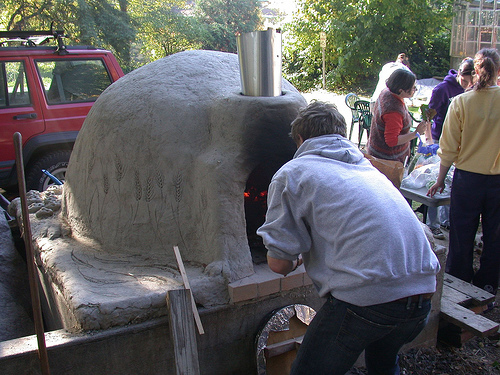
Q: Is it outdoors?
A: Yes, it is outdoors.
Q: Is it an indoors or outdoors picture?
A: It is outdoors.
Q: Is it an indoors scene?
A: No, it is outdoors.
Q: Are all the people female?
A: No, they are both male and female.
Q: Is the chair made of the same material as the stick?
A: No, the chair is made of plastic and the stick is made of wood.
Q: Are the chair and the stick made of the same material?
A: No, the chair is made of plastic and the stick is made of wood.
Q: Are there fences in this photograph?
A: No, there are no fences.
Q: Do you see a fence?
A: No, there are no fences.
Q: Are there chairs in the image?
A: Yes, there is a chair.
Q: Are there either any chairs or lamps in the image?
A: Yes, there is a chair.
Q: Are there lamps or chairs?
A: Yes, there is a chair.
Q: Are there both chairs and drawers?
A: No, there is a chair but no drawers.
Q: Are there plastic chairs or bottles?
A: Yes, there is a plastic chair.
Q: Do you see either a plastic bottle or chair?
A: Yes, there is a plastic chair.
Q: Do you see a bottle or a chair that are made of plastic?
A: Yes, the chair is made of plastic.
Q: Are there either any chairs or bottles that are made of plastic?
A: Yes, the chair is made of plastic.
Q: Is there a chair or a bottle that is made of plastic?
A: Yes, the chair is made of plastic.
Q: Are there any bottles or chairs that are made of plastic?
A: Yes, the chair is made of plastic.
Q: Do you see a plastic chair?
A: Yes, there is a chair that is made of plastic.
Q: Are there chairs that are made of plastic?
A: Yes, there is a chair that is made of plastic.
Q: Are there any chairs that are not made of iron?
A: Yes, there is a chair that is made of plastic.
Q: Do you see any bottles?
A: No, there are no bottles.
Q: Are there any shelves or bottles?
A: No, there are no bottles or shelves.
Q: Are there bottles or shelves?
A: No, there are no bottles or shelves.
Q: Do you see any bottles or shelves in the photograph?
A: No, there are no bottles or shelves.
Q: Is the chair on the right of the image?
A: Yes, the chair is on the right of the image.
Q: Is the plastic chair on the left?
A: No, the chair is on the right of the image.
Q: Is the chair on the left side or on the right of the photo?
A: The chair is on the right of the image.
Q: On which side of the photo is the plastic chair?
A: The chair is on the right of the image.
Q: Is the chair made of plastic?
A: Yes, the chair is made of plastic.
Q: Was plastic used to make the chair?
A: Yes, the chair is made of plastic.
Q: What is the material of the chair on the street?
A: The chair is made of plastic.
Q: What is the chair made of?
A: The chair is made of plastic.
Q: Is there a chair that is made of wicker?
A: No, there is a chair but it is made of plastic.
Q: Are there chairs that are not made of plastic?
A: No, there is a chair but it is made of plastic.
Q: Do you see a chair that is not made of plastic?
A: No, there is a chair but it is made of plastic.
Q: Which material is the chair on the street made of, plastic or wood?
A: The chair is made of plastic.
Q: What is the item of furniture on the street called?
A: The piece of furniture is a chair.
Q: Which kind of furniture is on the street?
A: The piece of furniture is a chair.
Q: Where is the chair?
A: The chair is on the street.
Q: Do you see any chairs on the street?
A: Yes, there is a chair on the street.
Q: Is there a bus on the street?
A: No, there is a chair on the street.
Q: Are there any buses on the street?
A: No, there is a chair on the street.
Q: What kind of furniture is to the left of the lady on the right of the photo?
A: The piece of furniture is a chair.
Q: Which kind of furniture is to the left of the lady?
A: The piece of furniture is a chair.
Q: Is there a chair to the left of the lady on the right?
A: Yes, there is a chair to the left of the lady.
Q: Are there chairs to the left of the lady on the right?
A: Yes, there is a chair to the left of the lady.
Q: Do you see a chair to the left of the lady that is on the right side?
A: Yes, there is a chair to the left of the lady.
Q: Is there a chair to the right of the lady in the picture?
A: No, the chair is to the left of the lady.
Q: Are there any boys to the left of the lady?
A: No, there is a chair to the left of the lady.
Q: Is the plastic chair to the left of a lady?
A: Yes, the chair is to the left of a lady.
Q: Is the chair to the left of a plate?
A: No, the chair is to the left of a lady.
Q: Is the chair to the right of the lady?
A: No, the chair is to the left of the lady.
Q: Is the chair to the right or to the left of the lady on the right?
A: The chair is to the left of the lady.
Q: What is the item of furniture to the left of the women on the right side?
A: The piece of furniture is a chair.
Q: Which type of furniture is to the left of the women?
A: The piece of furniture is a chair.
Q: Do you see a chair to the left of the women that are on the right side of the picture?
A: Yes, there is a chair to the left of the women.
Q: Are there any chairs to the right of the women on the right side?
A: No, the chair is to the left of the women.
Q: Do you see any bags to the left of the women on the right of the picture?
A: No, there is a chair to the left of the women.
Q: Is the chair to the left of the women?
A: Yes, the chair is to the left of the women.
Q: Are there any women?
A: Yes, there are women.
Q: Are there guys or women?
A: Yes, there are women.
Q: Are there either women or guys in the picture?
A: Yes, there are women.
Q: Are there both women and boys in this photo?
A: No, there are women but no boys.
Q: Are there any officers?
A: No, there are no officers.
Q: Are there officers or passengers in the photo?
A: No, there are no officers or passengers.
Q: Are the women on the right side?
A: Yes, the women are on the right of the image.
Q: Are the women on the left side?
A: No, the women are on the right of the image.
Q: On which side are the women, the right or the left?
A: The women are on the right of the image.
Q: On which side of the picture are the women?
A: The women are on the right of the image.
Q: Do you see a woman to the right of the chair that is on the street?
A: Yes, there are women to the right of the chair.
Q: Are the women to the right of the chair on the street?
A: Yes, the women are to the right of the chair.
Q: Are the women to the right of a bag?
A: No, the women are to the right of the chair.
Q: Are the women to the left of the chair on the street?
A: No, the women are to the right of the chair.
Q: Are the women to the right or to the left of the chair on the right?
A: The women are to the right of the chair.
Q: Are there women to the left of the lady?
A: Yes, there are women to the left of the lady.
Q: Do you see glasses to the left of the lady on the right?
A: No, there are women to the left of the lady.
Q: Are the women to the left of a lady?
A: Yes, the women are to the left of a lady.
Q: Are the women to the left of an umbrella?
A: No, the women are to the left of a lady.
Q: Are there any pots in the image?
A: No, there are no pots.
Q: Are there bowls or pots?
A: No, there are no pots or bowls.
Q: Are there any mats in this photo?
A: No, there are no mats.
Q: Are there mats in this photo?
A: No, there are no mats.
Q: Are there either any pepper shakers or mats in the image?
A: No, there are no mats or pepper shakers.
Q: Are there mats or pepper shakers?
A: No, there are no mats or pepper shakers.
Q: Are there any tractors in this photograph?
A: No, there are no tractors.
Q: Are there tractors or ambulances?
A: No, there are no tractors or ambulances.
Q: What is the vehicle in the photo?
A: The vehicle is a car.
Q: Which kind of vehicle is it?
A: The vehicle is a car.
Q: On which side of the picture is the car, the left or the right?
A: The car is on the left of the image.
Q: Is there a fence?
A: No, there are no fences.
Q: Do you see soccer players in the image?
A: No, there are no soccer players.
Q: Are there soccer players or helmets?
A: No, there are no soccer players or helmets.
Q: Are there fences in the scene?
A: No, there are no fences.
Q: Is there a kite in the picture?
A: No, there are no kites.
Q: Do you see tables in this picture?
A: Yes, there is a table.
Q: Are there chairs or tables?
A: Yes, there is a table.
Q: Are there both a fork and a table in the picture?
A: No, there is a table but no forks.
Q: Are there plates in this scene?
A: No, there are no plates.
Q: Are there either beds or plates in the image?
A: No, there are no plates or beds.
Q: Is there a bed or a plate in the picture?
A: No, there are no plates or beds.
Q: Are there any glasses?
A: No, there are no glasses.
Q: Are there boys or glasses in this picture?
A: No, there are no glasses or boys.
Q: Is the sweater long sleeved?
A: Yes, the sweater is long sleeved.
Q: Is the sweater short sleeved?
A: No, the sweater is long sleeved.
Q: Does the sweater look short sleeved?
A: No, the sweater is long sleeved.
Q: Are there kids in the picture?
A: No, there are no kids.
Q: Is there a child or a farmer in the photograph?
A: No, there are no children or farmers.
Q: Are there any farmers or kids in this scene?
A: No, there are no kids or farmers.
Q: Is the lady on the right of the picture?
A: Yes, the lady is on the right of the image.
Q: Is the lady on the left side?
A: No, the lady is on the right of the image.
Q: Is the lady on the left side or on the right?
A: The lady is on the right of the image.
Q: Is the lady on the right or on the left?
A: The lady is on the right of the image.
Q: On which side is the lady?
A: The lady is on the right of the image.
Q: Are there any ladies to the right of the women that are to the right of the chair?
A: Yes, there is a lady to the right of the women.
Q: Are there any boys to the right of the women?
A: No, there is a lady to the right of the women.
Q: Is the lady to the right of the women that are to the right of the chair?
A: Yes, the lady is to the right of the women.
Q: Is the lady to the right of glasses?
A: No, the lady is to the right of the women.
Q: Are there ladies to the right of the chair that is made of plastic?
A: Yes, there is a lady to the right of the chair.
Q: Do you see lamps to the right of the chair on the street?
A: No, there is a lady to the right of the chair.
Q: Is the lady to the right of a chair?
A: Yes, the lady is to the right of a chair.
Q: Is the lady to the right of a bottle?
A: No, the lady is to the right of a chair.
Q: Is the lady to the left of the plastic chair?
A: No, the lady is to the right of the chair.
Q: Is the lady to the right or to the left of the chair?
A: The lady is to the right of the chair.